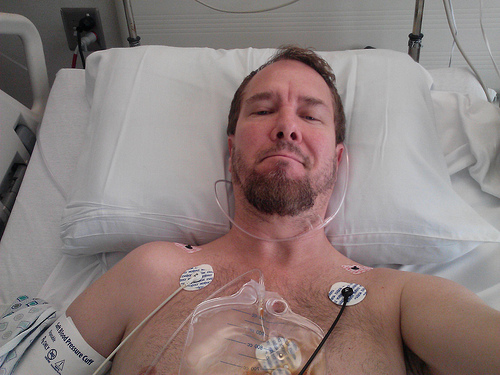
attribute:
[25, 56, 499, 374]
man — shirtless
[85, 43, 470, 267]
pillow — white, large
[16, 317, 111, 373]
blood pressure cuff — white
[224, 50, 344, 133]
hair — brown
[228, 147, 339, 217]
beard — brown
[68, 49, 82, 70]
cord — red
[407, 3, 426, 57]
bedpost — silver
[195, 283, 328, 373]
medical bag — plastic, clear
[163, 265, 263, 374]
tube — plastic, clear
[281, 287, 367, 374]
wire — black, white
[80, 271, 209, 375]
wire — white